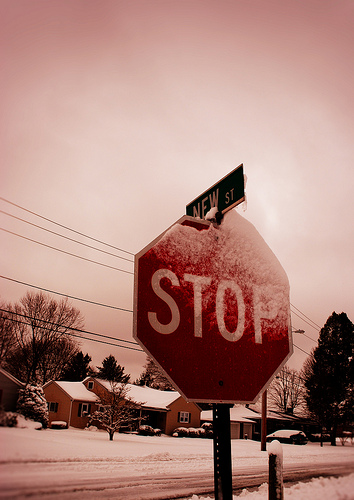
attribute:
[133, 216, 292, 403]
sign — red, octagon, dark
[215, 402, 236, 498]
pole — green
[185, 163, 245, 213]
sign — green, small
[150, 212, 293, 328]
snow — white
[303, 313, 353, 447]
tree — green, tall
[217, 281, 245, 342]
letter — white, large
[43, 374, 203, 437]
house — tan, brown, brick